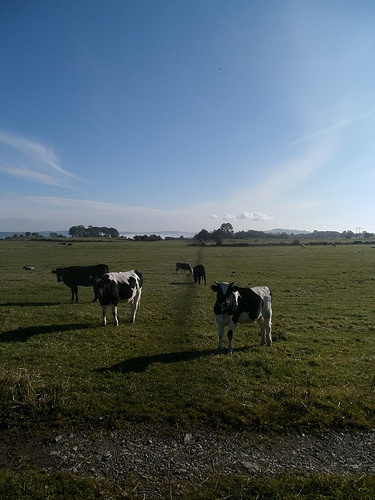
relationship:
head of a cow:
[211, 280, 238, 311] [209, 279, 274, 353]